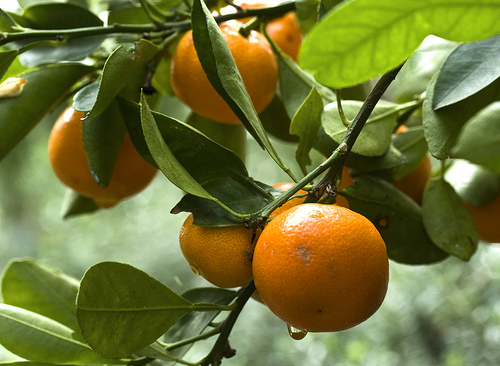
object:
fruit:
[169, 17, 277, 125]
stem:
[235, 21, 257, 39]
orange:
[168, 17, 280, 125]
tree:
[32, 33, 490, 361]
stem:
[312, 148, 346, 205]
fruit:
[250, 202, 389, 333]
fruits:
[176, 208, 269, 286]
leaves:
[4, 1, 166, 182]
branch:
[0, 0, 299, 46]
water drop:
[286, 322, 312, 343]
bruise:
[291, 238, 315, 264]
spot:
[316, 307, 323, 313]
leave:
[76, 18, 196, 68]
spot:
[185, 145, 219, 165]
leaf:
[138, 90, 279, 227]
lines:
[205, 173, 259, 222]